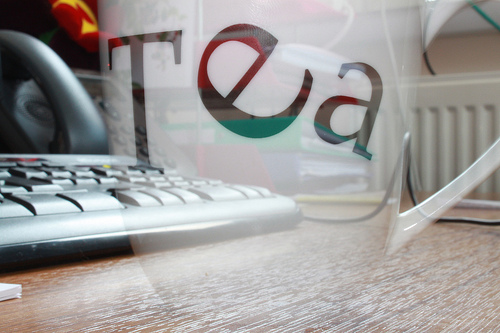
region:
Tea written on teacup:
[115, 14, 383, 194]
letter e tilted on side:
[193, 18, 314, 143]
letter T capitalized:
[93, 23, 188, 178]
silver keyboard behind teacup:
[1, 145, 301, 274]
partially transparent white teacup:
[102, 0, 499, 312]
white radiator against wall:
[353, 65, 498, 198]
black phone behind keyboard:
[3, 27, 155, 158]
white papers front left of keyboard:
[0, 271, 25, 306]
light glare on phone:
[17, 33, 146, 153]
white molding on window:
[191, 0, 498, 36]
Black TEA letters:
[94, 15, 408, 200]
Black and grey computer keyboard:
[3, 92, 343, 282]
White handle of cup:
[390, 4, 499, 255]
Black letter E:
[193, 21, 312, 147]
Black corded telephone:
[2, 25, 228, 221]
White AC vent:
[339, 64, 498, 202]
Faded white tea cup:
[87, 0, 486, 332]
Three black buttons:
[0, 184, 118, 254]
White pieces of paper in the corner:
[0, 276, 28, 301]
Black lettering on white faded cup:
[97, 24, 392, 223]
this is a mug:
[109, 11, 298, 246]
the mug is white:
[48, 139, 308, 221]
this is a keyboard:
[94, 176, 157, 263]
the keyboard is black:
[110, 168, 166, 259]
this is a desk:
[143, 284, 179, 311]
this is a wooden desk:
[112, 271, 189, 331]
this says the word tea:
[186, 106, 400, 140]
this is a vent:
[388, 54, 490, 204]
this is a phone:
[47, 68, 148, 195]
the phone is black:
[28, 47, 98, 135]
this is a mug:
[157, 0, 344, 330]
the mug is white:
[150, 64, 378, 330]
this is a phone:
[78, 109, 116, 151]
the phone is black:
[0, 101, 163, 133]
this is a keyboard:
[58, 132, 197, 329]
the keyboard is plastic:
[33, 149, 128, 244]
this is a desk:
[95, 245, 197, 326]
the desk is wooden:
[99, 284, 124, 327]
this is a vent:
[432, 92, 482, 163]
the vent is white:
[441, 149, 476, 173]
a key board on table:
[10, 123, 305, 300]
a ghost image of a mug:
[89, 11, 424, 326]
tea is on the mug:
[88, 28, 465, 221]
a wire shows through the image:
[305, 118, 410, 239]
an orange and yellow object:
[38, 0, 132, 70]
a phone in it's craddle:
[7, 12, 116, 174]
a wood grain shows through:
[111, 248, 478, 309]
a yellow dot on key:
[98, 158, 115, 175]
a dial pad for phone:
[96, 94, 167, 182]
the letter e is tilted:
[193, 17, 330, 159]